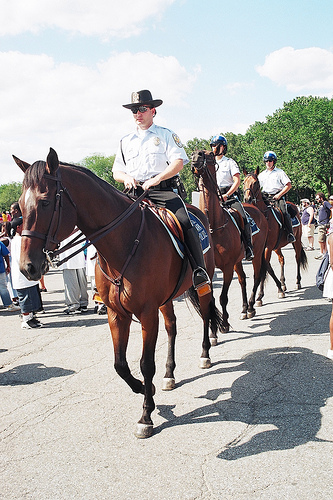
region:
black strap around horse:
[101, 269, 136, 292]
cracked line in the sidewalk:
[186, 448, 216, 479]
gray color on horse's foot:
[122, 417, 160, 436]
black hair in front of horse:
[14, 161, 53, 181]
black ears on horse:
[39, 144, 68, 173]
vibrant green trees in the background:
[242, 109, 332, 145]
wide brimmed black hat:
[105, 77, 178, 118]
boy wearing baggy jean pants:
[11, 281, 44, 315]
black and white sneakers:
[12, 314, 67, 335]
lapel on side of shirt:
[171, 126, 187, 157]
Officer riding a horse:
[112, 88, 209, 285]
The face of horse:
[9, 149, 68, 283]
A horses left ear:
[42, 145, 65, 175]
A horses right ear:
[8, 152, 33, 172]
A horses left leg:
[130, 280, 162, 445]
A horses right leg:
[99, 300, 160, 400]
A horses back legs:
[156, 266, 223, 394]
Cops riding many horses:
[10, 83, 303, 434]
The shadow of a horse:
[154, 329, 329, 469]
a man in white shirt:
[2, 214, 49, 330]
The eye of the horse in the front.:
[40, 199, 48, 208]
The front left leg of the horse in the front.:
[104, 307, 141, 395]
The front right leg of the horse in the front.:
[127, 307, 156, 435]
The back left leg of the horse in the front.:
[158, 304, 177, 390]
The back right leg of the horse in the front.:
[199, 282, 211, 366]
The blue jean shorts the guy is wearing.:
[15, 289, 42, 314]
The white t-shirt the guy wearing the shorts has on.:
[7, 232, 36, 288]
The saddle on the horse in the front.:
[135, 184, 191, 237]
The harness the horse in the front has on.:
[16, 159, 74, 272]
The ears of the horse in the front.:
[10, 151, 62, 167]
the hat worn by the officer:
[112, 83, 166, 109]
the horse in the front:
[3, 145, 233, 450]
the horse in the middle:
[176, 137, 273, 333]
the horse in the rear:
[242, 163, 313, 309]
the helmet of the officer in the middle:
[208, 134, 234, 150]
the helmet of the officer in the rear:
[258, 147, 281, 157]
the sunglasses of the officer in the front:
[129, 103, 151, 113]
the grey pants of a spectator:
[60, 267, 93, 315]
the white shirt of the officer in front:
[104, 122, 189, 182]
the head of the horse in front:
[6, 145, 80, 299]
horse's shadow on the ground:
[182, 343, 331, 466]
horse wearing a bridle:
[5, 156, 77, 279]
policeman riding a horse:
[107, 86, 211, 302]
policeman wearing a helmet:
[258, 149, 297, 243]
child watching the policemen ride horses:
[5, 211, 50, 339]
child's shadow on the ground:
[23, 310, 115, 338]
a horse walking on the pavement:
[6, 146, 234, 434]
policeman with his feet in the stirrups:
[112, 87, 223, 307]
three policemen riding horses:
[9, 85, 309, 380]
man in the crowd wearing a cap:
[297, 197, 318, 254]